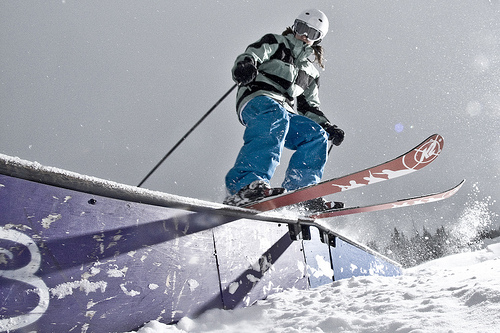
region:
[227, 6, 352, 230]
a person sking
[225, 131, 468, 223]
a couple of red skies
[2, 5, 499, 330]
a scene outside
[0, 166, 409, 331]
a purple and blue ramp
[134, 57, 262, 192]
a black pole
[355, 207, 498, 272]
a row of trees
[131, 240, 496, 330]
a white snow patch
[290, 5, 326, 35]
a white helmet here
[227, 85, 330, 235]
a pair of blue pants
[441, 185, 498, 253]
snow being kicked up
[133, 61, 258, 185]
a ski pole in the man's right hand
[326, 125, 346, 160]
the top of the ski pole in the skier's left hand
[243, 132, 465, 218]
the front half of two red and white skies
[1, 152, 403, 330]
a blue and silver ramp on a mountain slope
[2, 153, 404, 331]
ramp on the snowy mountain slope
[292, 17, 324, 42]
silver goggles protecting the skier's eye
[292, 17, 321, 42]
a skier wearing goggles to protect the eyes from the wind and snow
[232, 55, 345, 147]
black winter gloves on the skier's hands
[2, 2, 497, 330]
a skier skiing across a ramp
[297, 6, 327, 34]
a white hard helmet on the skier's head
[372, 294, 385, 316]
the snow is white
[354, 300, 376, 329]
the snow is white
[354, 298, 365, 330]
the snow is white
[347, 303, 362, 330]
the snow is white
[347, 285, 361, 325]
the snow is white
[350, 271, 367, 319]
the snow is white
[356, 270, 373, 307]
the snow is white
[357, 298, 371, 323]
the snow is white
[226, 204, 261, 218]
part of a metal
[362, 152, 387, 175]
edge of a bioard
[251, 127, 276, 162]
part of a trouser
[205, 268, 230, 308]
part of a glass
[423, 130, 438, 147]
edge of a board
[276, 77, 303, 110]
part of a jacket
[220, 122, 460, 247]
red skis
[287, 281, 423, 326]
snow with tracks in it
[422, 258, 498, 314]
white snow on the ground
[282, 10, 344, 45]
a white helmet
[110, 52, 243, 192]
a long black ski pole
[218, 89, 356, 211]
blue ski pants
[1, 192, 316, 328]
shadow of the skis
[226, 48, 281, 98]
black winter ski gloves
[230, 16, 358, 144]
a striped jacket on the skier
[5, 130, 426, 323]
a ramp in the snow